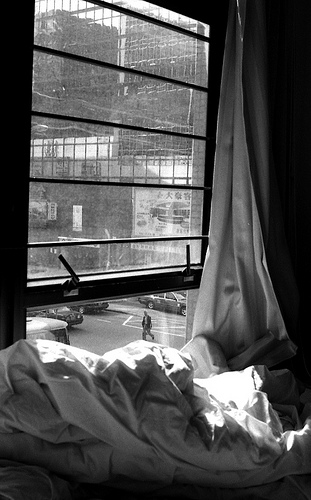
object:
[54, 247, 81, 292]
handle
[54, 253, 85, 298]
window lock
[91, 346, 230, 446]
lamp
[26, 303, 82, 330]
car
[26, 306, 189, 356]
road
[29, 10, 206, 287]
pane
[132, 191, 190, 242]
billboard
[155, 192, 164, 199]
writing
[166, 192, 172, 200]
writing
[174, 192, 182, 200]
writing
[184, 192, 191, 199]
writing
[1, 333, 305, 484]
white blanke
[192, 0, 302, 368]
curtain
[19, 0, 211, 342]
window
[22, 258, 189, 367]
street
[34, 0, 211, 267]
wall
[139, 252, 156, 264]
chairs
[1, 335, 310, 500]
blanket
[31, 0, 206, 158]
white pane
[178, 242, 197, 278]
window lock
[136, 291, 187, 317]
car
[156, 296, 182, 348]
sun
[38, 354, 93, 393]
wrinkle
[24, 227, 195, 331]
view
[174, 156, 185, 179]
pane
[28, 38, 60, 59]
pane